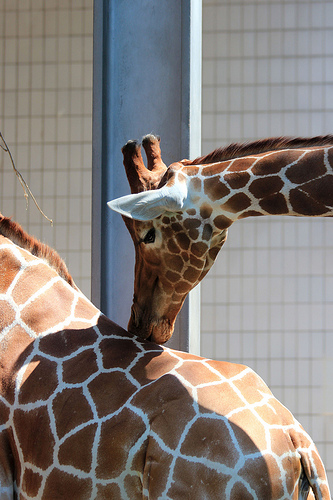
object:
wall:
[1, 3, 331, 477]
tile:
[295, 357, 310, 387]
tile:
[266, 330, 283, 360]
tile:
[243, 274, 255, 301]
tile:
[68, 169, 82, 195]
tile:
[28, 116, 41, 144]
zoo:
[0, 2, 333, 500]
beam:
[92, 0, 202, 357]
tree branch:
[0, 131, 51, 225]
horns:
[122, 134, 164, 183]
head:
[104, 132, 231, 342]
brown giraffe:
[104, 131, 332, 345]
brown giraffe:
[1, 214, 332, 498]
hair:
[186, 132, 331, 166]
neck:
[203, 137, 332, 226]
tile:
[288, 351, 305, 391]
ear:
[106, 173, 189, 221]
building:
[0, 1, 332, 499]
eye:
[136, 226, 156, 247]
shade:
[4, 314, 273, 500]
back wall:
[14, 45, 72, 177]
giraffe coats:
[0, 217, 329, 493]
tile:
[293, 327, 313, 371]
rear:
[150, 344, 317, 498]